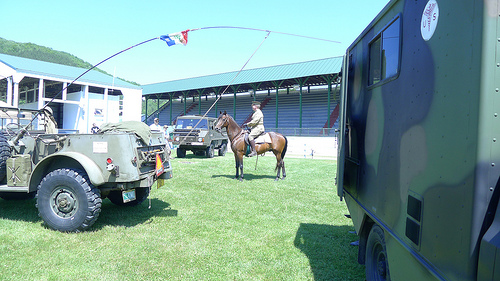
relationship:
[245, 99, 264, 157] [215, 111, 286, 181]
man on horse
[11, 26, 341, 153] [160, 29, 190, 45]
antenna has flag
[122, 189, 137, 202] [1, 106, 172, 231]
license plate on jeep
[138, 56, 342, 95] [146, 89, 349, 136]
room over grandstand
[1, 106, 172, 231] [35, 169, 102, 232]
jeep has tire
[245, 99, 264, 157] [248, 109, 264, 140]
man in uniform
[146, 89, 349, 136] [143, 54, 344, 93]
grandstand has roof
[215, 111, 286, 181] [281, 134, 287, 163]
horse has tail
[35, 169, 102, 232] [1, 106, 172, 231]
tire on jeep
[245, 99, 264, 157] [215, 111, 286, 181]
man riding horse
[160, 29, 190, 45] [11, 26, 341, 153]
flag on antenna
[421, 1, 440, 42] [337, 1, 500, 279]
symbol on troop carrier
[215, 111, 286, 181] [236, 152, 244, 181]
horse has front leg